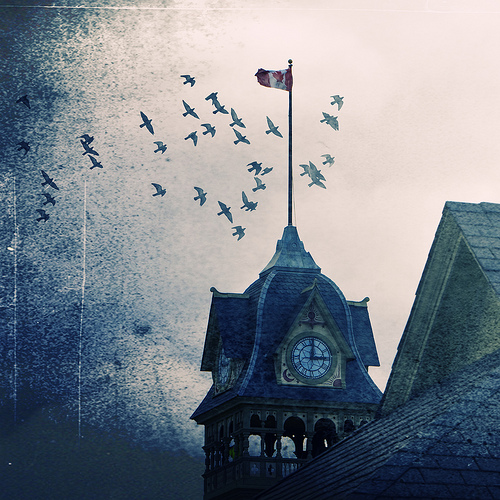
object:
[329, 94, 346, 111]
birds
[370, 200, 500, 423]
roof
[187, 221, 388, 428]
cupola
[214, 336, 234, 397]
clock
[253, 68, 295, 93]
flag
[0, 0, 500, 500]
sky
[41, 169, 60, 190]
black bird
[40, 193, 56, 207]
black bird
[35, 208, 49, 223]
black bird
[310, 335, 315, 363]
hand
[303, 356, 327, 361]
hand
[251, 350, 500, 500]
roof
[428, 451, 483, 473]
gray shingles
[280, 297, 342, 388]
clock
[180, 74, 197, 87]
birds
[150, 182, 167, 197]
black bird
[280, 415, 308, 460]
windows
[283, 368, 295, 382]
half moon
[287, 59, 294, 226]
flag pole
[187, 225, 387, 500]
building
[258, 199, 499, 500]
building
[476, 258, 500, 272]
shingle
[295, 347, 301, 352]
roman numerals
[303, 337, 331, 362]
3 o'clock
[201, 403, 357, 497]
viewing area